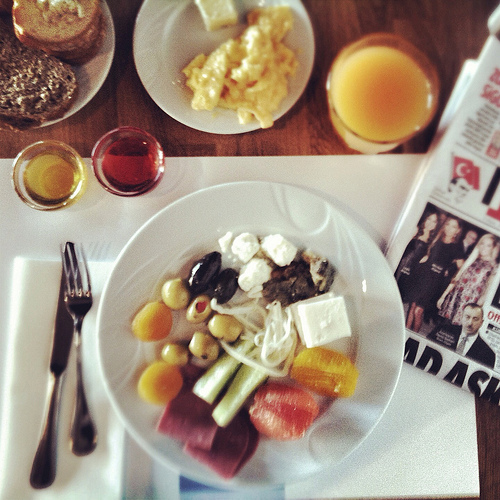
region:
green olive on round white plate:
[187, 295, 210, 321]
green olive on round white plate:
[162, 278, 190, 309]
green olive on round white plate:
[206, 315, 242, 342]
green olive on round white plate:
[187, 331, 220, 359]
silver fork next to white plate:
[59, 240, 98, 455]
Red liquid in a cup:
[82, 122, 171, 199]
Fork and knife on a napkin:
[24, 234, 114, 499]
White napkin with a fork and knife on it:
[8, 249, 123, 498]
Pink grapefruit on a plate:
[245, 379, 317, 439]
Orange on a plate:
[291, 343, 365, 396]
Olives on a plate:
[135, 278, 242, 373]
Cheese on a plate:
[223, 208, 300, 308]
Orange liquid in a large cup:
[324, 26, 444, 160]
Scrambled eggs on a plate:
[162, 18, 311, 130]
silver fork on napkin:
[43, 239, 108, 463]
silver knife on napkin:
[23, 227, 84, 492]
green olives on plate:
[159, 271, 236, 377]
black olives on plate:
[173, 236, 253, 311]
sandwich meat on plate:
[155, 358, 283, 495]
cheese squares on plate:
[288, 295, 368, 350]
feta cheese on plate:
[203, 211, 294, 300]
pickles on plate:
[182, 341, 291, 431]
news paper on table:
[372, 30, 499, 408]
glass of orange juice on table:
[316, 22, 443, 171]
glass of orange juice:
[323, 30, 450, 168]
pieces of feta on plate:
[214, 225, 312, 300]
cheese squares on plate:
[278, 285, 357, 352]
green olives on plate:
[146, 250, 250, 378]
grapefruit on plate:
[242, 370, 348, 441]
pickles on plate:
[188, 345, 290, 430]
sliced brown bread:
[1, 25, 87, 145]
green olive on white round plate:
[160, 277, 189, 308]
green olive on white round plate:
[187, 293, 213, 323]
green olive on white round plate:
[208, 314, 243, 345]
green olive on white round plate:
[186, 331, 221, 362]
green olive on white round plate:
[161, 343, 189, 364]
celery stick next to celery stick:
[189, 336, 243, 404]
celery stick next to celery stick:
[211, 345, 270, 426]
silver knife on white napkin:
[28, 240, 76, 489]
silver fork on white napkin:
[58, 243, 96, 455]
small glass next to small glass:
[10, 141, 85, 210]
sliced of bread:
[0, 10, 97, 150]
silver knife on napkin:
[19, 236, 99, 498]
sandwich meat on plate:
[149, 363, 285, 493]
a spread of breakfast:
[4, 2, 488, 467]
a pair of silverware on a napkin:
[12, 238, 129, 488]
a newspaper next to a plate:
[370, 39, 498, 362]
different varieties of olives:
[147, 250, 237, 363]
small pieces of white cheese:
[220, 224, 295, 300]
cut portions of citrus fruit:
[237, 342, 366, 451]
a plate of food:
[89, 195, 426, 490]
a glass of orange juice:
[326, 19, 444, 176]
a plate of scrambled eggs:
[122, 5, 322, 140]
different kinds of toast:
[0, 10, 122, 116]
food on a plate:
[295, 350, 355, 392]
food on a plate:
[260, 387, 310, 435]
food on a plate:
[172, 408, 240, 463]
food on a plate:
[138, 363, 193, 395]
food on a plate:
[126, 295, 182, 342]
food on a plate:
[165, 245, 221, 290]